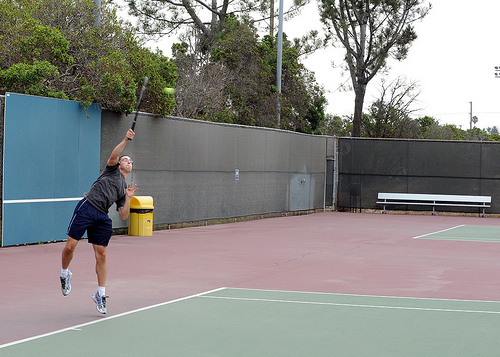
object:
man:
[59, 127, 140, 315]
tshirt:
[83, 161, 130, 216]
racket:
[128, 75, 151, 141]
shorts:
[65, 198, 114, 247]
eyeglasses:
[120, 158, 134, 163]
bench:
[375, 192, 492, 217]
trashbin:
[127, 195, 156, 238]